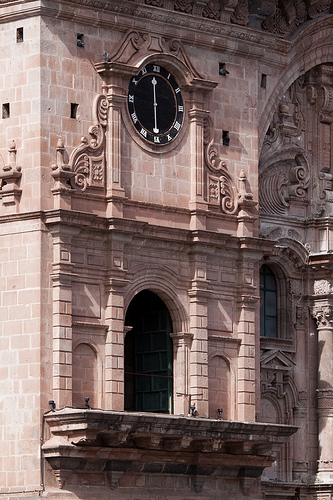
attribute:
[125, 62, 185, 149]
clock — black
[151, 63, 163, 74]
number — white, roman numeral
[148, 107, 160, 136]
hand — white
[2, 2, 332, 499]
building — gray, church, brick, brown, beige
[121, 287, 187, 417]
window — arched, closed, open, black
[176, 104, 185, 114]
number — roman numeral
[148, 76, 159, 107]
hand — white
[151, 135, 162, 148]
six — white